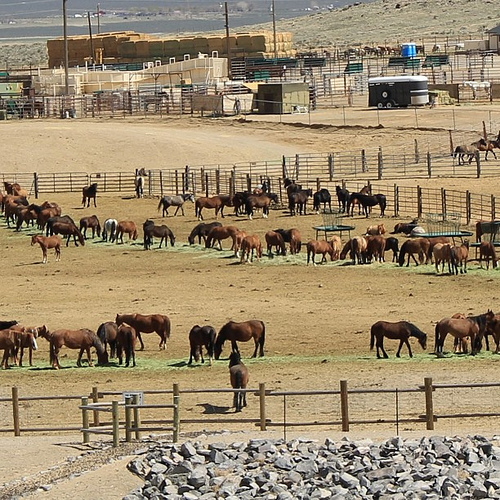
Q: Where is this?
A: This is at the farm.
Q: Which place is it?
A: It is a farm.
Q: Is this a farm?
A: Yes, it is a farm.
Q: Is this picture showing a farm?
A: Yes, it is showing a farm.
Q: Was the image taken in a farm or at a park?
A: It was taken at a farm.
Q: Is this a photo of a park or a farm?
A: It is showing a farm.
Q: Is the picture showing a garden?
A: No, the picture is showing a farm.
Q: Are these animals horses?
A: Yes, all the animals are horses.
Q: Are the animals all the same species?
A: Yes, all the animals are horses.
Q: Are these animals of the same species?
A: Yes, all the animals are horses.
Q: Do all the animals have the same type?
A: Yes, all the animals are horses.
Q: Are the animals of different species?
A: No, all the animals are horses.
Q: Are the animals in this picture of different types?
A: No, all the animals are horses.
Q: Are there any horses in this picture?
A: Yes, there are horses.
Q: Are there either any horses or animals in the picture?
A: Yes, there are horses.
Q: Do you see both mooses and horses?
A: No, there are horses but no mooses.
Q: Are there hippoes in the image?
A: No, there are no hippoes.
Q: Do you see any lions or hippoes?
A: No, there are no hippoes or lions.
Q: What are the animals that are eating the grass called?
A: The animals are horses.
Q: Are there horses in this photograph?
A: Yes, there is a horse.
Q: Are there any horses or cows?
A: Yes, there is a horse.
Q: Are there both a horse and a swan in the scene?
A: No, there is a horse but no swans.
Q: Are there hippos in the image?
A: No, there are no hippos.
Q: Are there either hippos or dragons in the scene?
A: No, there are no hippos or dragons.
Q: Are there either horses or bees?
A: Yes, there is a horse.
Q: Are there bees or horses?
A: Yes, there is a horse.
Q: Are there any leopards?
A: No, there are no leopards.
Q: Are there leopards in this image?
A: No, there are no leopards.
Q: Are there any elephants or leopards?
A: No, there are no leopards or elephants.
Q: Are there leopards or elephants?
A: No, there are no leopards or elephants.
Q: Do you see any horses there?
A: Yes, there are horses.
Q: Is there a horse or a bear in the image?
A: Yes, there are horses.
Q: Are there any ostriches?
A: No, there are no ostriches.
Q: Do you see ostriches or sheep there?
A: No, there are no ostriches or sheep.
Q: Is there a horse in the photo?
A: Yes, there are horses.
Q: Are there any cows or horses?
A: Yes, there are horses.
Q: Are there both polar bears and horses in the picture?
A: No, there are horses but no polar bears.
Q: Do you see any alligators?
A: No, there are no alligators.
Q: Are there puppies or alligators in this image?
A: No, there are no alligators or puppies.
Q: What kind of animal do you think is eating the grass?
A: The animals are horses.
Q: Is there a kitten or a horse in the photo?
A: Yes, there are horses.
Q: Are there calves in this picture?
A: No, there are no calves.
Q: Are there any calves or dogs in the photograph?
A: No, there are no calves or dogs.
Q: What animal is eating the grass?
A: The horses are eating the grass.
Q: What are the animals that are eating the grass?
A: The animals are horses.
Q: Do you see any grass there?
A: Yes, there is grass.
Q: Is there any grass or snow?
A: Yes, there is grass.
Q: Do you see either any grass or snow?
A: Yes, there is grass.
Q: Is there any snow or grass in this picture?
A: Yes, there is grass.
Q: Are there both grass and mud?
A: No, there is grass but no mud.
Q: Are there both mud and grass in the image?
A: No, there is grass but no mud.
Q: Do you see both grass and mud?
A: No, there is grass but no mud.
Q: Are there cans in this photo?
A: No, there are no cans.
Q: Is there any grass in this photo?
A: Yes, there is grass.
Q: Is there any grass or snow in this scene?
A: Yes, there is grass.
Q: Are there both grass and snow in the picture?
A: No, there is grass but no snow.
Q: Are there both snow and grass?
A: No, there is grass but no snow.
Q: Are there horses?
A: Yes, there is a horse.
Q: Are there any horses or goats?
A: Yes, there is a horse.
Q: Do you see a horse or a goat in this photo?
A: Yes, there is a horse.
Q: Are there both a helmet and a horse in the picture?
A: No, there is a horse but no helmets.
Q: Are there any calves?
A: No, there are no calves.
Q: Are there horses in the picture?
A: Yes, there is a horse.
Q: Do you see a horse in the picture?
A: Yes, there is a horse.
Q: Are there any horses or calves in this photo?
A: Yes, there is a horse.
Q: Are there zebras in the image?
A: No, there are no zebras.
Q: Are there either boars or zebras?
A: No, there are no zebras or boars.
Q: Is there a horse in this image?
A: Yes, there are horses.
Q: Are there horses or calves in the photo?
A: Yes, there are horses.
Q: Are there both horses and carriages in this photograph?
A: No, there are horses but no carriages.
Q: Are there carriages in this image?
A: No, there are no carriages.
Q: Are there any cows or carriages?
A: No, there are no carriages or cows.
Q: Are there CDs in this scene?
A: No, there are no cds.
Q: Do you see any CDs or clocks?
A: No, there are no CDs or clocks.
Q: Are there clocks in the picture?
A: No, there are no clocks.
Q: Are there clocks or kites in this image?
A: No, there are no clocks or kites.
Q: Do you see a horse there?
A: Yes, there is a horse.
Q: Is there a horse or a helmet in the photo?
A: Yes, there is a horse.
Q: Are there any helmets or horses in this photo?
A: Yes, there is a horse.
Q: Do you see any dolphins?
A: No, there are no dolphins.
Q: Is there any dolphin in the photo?
A: No, there are no dolphins.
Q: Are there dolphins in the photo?
A: No, there are no dolphins.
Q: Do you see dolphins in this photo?
A: No, there are no dolphins.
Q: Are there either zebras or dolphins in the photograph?
A: No, there are no dolphins or zebras.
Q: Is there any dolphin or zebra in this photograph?
A: No, there are no dolphins or zebras.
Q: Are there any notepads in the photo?
A: No, there are no notepads.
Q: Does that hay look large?
A: Yes, the hay is large.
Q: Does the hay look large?
A: Yes, the hay is large.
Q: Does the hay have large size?
A: Yes, the hay is large.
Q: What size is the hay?
A: The hay is large.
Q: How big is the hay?
A: The hay is large.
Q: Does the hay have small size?
A: No, the hay is large.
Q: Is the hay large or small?
A: The hay is large.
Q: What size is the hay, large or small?
A: The hay is large.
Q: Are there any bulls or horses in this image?
A: Yes, there is a horse.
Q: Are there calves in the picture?
A: No, there are no calves.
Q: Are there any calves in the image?
A: No, there are no calves.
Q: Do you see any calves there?
A: No, there are no calves.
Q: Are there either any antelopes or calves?
A: No, there are no calves or antelopes.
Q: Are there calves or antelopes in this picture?
A: No, there are no calves or antelopes.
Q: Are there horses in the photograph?
A: Yes, there is a horse.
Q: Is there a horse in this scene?
A: Yes, there is a horse.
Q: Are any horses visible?
A: Yes, there is a horse.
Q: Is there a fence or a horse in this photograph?
A: Yes, there is a horse.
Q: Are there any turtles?
A: No, there are no turtles.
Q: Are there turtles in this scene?
A: No, there are no turtles.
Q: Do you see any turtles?
A: No, there are no turtles.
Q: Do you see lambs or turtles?
A: No, there are no turtles or lambs.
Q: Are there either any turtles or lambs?
A: No, there are no turtles or lambs.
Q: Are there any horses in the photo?
A: Yes, there is a horse.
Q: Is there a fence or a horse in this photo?
A: Yes, there is a horse.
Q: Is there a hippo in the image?
A: No, there are no hippos.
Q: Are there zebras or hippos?
A: No, there are no hippos or zebras.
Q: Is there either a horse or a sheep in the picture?
A: Yes, there are horses.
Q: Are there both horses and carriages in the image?
A: No, there are horses but no carriages.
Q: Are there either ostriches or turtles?
A: No, there are no turtles or ostriches.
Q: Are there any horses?
A: Yes, there are horses.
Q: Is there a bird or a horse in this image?
A: Yes, there are horses.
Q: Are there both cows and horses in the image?
A: No, there are horses but no cows.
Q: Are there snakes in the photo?
A: No, there are no snakes.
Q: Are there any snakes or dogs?
A: No, there are no snakes or dogs.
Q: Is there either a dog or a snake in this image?
A: No, there are no snakes or dogs.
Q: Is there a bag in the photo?
A: No, there are no bags.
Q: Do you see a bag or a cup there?
A: No, there are no bags or cups.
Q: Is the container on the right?
A: Yes, the container is on the right of the image.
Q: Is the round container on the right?
A: Yes, the container is on the right of the image.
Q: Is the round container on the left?
A: No, the container is on the right of the image.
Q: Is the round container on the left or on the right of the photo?
A: The container is on the right of the image.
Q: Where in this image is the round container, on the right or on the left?
A: The container is on the right of the image.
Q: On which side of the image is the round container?
A: The container is on the right of the image.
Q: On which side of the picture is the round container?
A: The container is on the right of the image.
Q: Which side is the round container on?
A: The container is on the right of the image.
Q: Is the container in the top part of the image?
A: Yes, the container is in the top of the image.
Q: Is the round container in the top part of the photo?
A: Yes, the container is in the top of the image.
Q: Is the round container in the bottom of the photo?
A: No, the container is in the top of the image.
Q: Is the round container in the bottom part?
A: No, the container is in the top of the image.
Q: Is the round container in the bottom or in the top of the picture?
A: The container is in the top of the image.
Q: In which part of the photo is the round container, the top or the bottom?
A: The container is in the top of the image.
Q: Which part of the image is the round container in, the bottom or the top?
A: The container is in the top of the image.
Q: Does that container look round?
A: Yes, the container is round.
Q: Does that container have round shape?
A: Yes, the container is round.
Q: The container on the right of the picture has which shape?
A: The container is round.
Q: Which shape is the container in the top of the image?
A: The container is round.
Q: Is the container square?
A: No, the container is round.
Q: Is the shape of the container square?
A: No, the container is round.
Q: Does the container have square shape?
A: No, the container is round.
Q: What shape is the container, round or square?
A: The container is round.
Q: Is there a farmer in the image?
A: No, there are no farmers.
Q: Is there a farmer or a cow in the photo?
A: No, there are no farmers or cows.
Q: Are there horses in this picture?
A: Yes, there is a horse.